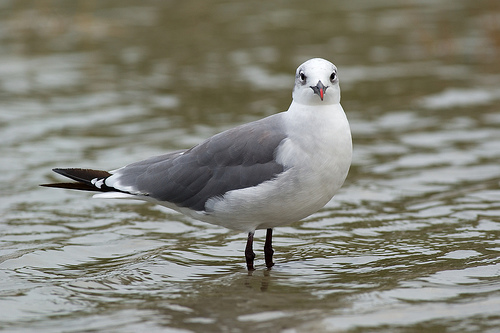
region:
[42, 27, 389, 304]
the bird is gray and white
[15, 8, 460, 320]
the water is brown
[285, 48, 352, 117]
the bird has an orange beak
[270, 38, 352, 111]
the bird has two eyes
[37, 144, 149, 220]
the bird has a black tail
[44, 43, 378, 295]
the bird has its legs in the water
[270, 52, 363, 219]
the bird's chest is white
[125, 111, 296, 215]
the bird's wing is gray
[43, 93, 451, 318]
the water has ripples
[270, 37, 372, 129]
the bird's head is white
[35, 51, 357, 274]
a bird with an orange beak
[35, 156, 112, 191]
Black and white tail feathers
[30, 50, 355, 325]
a bird standing in water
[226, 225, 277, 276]
a pair of black bird's legs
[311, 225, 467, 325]
murky water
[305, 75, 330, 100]
an orange bird's beak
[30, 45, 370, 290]
a bird looking into camera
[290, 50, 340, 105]
The head of a bird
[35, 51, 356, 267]
a black gray and white bird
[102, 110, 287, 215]
gray wings of a bird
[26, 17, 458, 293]
bird standing in the water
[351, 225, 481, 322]
ripples in the water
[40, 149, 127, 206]
black tail feathers of bird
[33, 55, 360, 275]
beautiful grey, white and black bird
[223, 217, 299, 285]
black legs on bird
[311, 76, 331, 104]
red colored beak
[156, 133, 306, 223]
gray colored wings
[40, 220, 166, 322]
slightly choppy brownish colored water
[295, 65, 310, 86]
black colored eye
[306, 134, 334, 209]
white colored feathers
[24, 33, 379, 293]
A bird standing in water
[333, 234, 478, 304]
A patch of brown water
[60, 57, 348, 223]
A bird with white, grey and black plumage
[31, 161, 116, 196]
The tail feathers of a bird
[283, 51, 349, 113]
A bird looking at the camera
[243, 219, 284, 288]
Black bird legs standing in water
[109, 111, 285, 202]
A bird with grey wing feathers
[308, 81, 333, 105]
A bird with a red beak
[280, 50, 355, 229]
A bird with white breast plumage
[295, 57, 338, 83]
Th eyes of a bird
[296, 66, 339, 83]
The bird's eyes are black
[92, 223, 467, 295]
The bird is standing in calm water.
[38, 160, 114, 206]
The bird's little tail is black.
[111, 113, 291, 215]
The bird's wing is grey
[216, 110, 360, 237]
The bird's chest and belly are white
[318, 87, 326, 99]
The bird has an orange stripe on it's beak.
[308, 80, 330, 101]
The bird's beak is black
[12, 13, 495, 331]
The water is a little choppy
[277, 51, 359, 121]
the bird's head is turned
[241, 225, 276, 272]
The bird's legs are black.